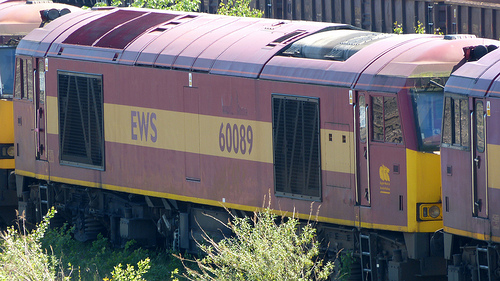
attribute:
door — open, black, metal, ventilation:
[268, 94, 324, 201]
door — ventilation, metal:
[54, 69, 106, 172]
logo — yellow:
[375, 161, 391, 183]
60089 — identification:
[218, 123, 256, 155]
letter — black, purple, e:
[128, 109, 139, 140]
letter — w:
[137, 110, 152, 141]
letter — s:
[149, 113, 158, 142]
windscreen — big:
[416, 93, 443, 150]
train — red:
[14, 5, 444, 259]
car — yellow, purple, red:
[13, 4, 493, 265]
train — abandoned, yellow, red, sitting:
[0, 9, 499, 268]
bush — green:
[170, 186, 345, 280]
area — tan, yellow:
[46, 94, 355, 173]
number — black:
[217, 119, 225, 152]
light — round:
[428, 202, 441, 220]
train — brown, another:
[67, 1, 499, 38]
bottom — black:
[14, 174, 443, 280]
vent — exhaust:
[265, 28, 307, 49]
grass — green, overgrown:
[2, 203, 356, 281]